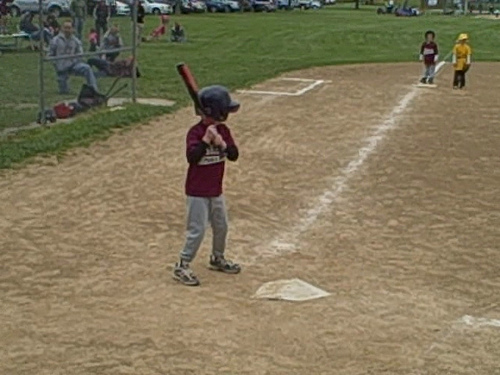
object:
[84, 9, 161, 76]
people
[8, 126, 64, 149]
grass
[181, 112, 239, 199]
shirt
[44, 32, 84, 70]
shirt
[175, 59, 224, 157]
baseball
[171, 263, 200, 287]
shoe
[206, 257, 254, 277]
shoes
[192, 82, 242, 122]
black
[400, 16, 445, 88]
boy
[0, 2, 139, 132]
fence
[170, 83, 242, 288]
batter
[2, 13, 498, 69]
grass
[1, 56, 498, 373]
baseball field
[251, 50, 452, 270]
line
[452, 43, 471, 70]
yellow shirt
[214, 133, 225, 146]
hand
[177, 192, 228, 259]
pants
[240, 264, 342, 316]
base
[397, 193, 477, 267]
dirt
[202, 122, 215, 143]
hand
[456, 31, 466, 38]
hat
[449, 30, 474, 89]
boy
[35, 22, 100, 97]
man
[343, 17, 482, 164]
pitch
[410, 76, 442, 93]
base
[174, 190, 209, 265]
leg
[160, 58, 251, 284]
batter